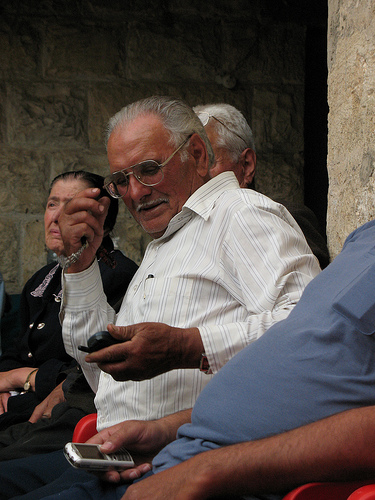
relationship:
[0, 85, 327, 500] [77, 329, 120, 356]
man has phone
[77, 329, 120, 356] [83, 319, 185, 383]
phone in hand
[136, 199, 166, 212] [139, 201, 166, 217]
mustache above lip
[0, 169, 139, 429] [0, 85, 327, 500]
woman next to man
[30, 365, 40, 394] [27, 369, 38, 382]
watch has band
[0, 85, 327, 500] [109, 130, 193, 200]
man has glasses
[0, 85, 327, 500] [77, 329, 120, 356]
man looking at phone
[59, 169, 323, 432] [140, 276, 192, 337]
shirt has pocket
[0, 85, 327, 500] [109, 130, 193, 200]
man wearing glasses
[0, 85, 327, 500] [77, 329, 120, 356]
man holding phone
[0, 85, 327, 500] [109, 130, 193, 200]
man wearing eyeglasses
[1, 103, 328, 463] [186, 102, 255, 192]
man has head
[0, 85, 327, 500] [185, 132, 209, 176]
man has ear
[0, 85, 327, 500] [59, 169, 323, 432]
man has shirt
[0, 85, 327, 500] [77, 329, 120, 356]
man has cellphone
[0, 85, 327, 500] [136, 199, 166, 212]
man has mustache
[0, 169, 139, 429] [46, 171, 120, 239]
woman has hair